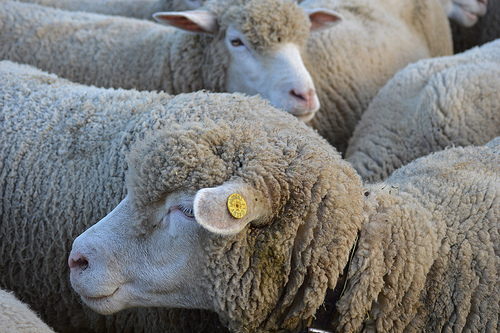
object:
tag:
[225, 192, 249, 219]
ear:
[192, 179, 270, 235]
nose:
[66, 250, 92, 273]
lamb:
[63, 88, 498, 333]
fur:
[118, 90, 500, 333]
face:
[64, 174, 218, 317]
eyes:
[176, 204, 195, 219]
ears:
[306, 8, 345, 31]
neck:
[306, 174, 421, 333]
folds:
[282, 230, 307, 279]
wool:
[0, 62, 345, 333]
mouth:
[74, 280, 134, 305]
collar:
[307, 227, 364, 332]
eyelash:
[178, 205, 195, 214]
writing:
[229, 194, 247, 217]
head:
[62, 87, 372, 333]